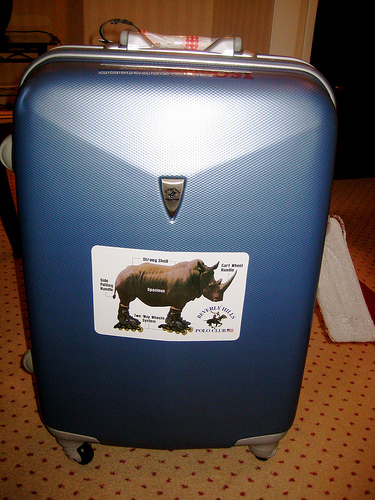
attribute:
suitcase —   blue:
[14, 26, 344, 478]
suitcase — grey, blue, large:
[18, 30, 318, 469]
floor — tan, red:
[115, 461, 324, 498]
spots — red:
[121, 471, 266, 498]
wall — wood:
[65, 4, 329, 59]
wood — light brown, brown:
[144, 10, 341, 59]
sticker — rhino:
[104, 250, 258, 347]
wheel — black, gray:
[58, 425, 107, 467]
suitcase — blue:
[23, 57, 310, 453]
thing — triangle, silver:
[145, 169, 211, 233]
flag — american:
[209, 324, 245, 338]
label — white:
[105, 229, 319, 374]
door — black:
[322, 15, 373, 129]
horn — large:
[213, 270, 251, 295]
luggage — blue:
[39, 57, 357, 468]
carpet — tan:
[262, 407, 369, 496]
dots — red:
[275, 435, 324, 473]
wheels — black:
[61, 429, 99, 455]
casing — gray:
[54, 432, 85, 460]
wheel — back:
[85, 439, 112, 468]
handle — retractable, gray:
[113, 34, 243, 89]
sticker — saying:
[91, 235, 252, 361]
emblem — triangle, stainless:
[147, 167, 218, 241]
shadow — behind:
[1, 240, 37, 312]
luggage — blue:
[19, 53, 341, 466]